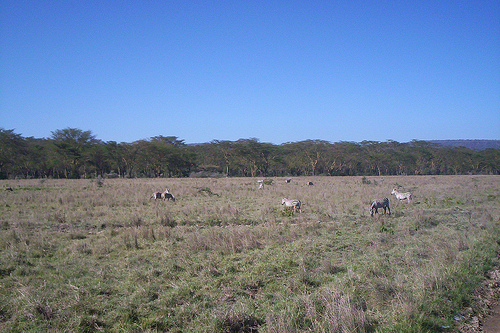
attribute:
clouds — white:
[280, 18, 498, 114]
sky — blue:
[155, 56, 330, 103]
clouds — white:
[385, 47, 418, 95]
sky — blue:
[4, 2, 498, 140]